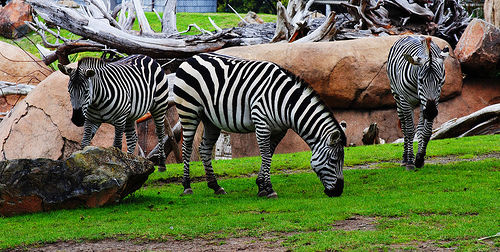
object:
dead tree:
[23, 0, 480, 60]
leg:
[255, 125, 272, 183]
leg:
[180, 121, 201, 179]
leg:
[198, 126, 217, 183]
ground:
[438, 142, 460, 162]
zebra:
[384, 32, 451, 172]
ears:
[439, 45, 449, 60]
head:
[404, 45, 449, 120]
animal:
[386, 35, 449, 170]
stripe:
[58, 52, 347, 147]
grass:
[3, 134, 500, 252]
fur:
[123, 75, 137, 90]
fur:
[393, 66, 407, 86]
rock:
[0, 146, 155, 218]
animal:
[58, 52, 347, 198]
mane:
[281, 69, 317, 94]